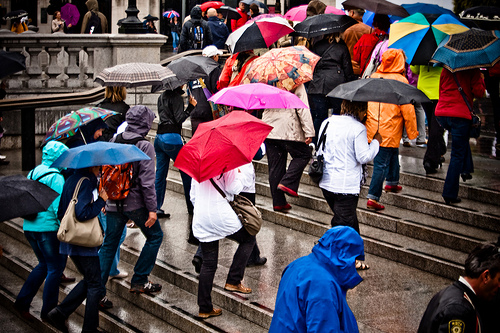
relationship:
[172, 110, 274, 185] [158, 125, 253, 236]
umbrella colorful and have abstract pattern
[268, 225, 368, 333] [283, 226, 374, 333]
jacket wearing a jacket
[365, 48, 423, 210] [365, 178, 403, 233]
woman in a raincoat and shoes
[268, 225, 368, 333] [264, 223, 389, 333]
jacket a jacket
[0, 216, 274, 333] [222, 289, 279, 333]
stairs stairs are made of stone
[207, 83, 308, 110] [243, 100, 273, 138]
umbrella a pink umbrella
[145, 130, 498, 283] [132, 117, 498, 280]
4 steps are 4 steps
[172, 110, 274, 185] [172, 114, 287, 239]
umbrella a red umbrella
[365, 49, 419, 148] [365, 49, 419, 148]
coat is orange rain coat is orange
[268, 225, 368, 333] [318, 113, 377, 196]
jacket wearing jacket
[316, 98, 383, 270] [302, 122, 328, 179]
woman carrying black bag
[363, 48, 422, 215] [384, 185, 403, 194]
woman wearing shoes